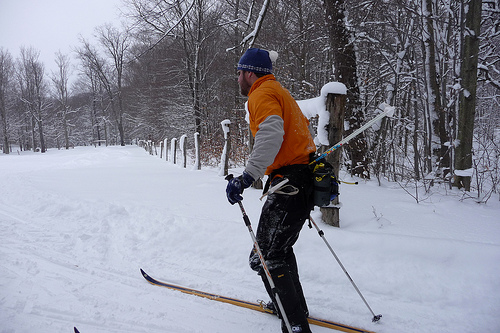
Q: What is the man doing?
A: Skiing.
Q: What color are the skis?
A: Yellow.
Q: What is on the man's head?
A: Hat.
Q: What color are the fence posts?
A: Brown.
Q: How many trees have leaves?
A: 0.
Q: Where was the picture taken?
A: Ski slopes.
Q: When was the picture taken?
A: Winter.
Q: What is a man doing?
A: Skiing.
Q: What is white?
A: Snow.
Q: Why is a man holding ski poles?
A: To ski.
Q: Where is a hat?
A: On man's head.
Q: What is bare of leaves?
A: Trees.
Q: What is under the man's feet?
A: Skis.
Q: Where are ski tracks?
A: On the snow.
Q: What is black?
A: Man's pants.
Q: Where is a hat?
A: On man's head.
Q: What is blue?
A: Hat.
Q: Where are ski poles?
A: In man's hands.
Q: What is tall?
A: Trees.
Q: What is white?
A: Snow.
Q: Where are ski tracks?
A: On the snow.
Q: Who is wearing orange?
A: Skiier.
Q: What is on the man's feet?
A: Skis.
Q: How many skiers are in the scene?
A: One.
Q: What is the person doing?
A: Snow skiing.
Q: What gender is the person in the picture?
A: Male.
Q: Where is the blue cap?
A: On the man's head.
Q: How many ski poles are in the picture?
A: Two.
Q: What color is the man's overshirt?
A: Orange.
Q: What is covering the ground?
A: Snow.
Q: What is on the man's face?
A: A beard.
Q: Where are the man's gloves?
A: On his hands.